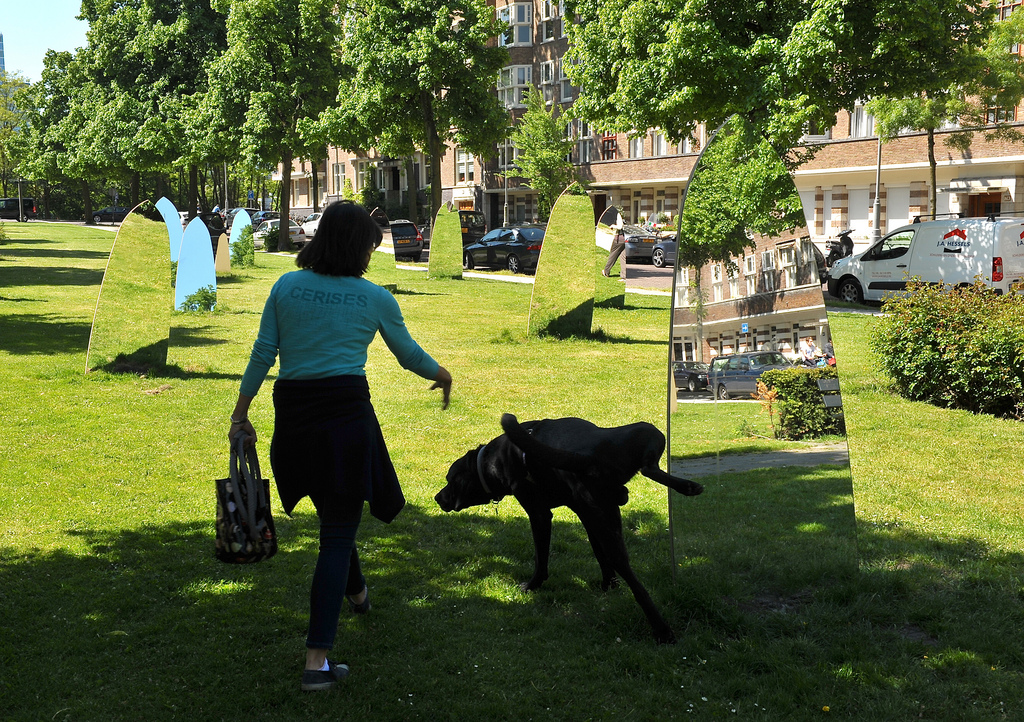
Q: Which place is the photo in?
A: It is at the park.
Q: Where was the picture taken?
A: It was taken at the park.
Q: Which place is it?
A: It is a park.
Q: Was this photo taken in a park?
A: Yes, it was taken in a park.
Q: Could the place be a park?
A: Yes, it is a park.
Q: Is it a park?
A: Yes, it is a park.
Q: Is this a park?
A: Yes, it is a park.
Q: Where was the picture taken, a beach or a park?
A: It was taken at a park.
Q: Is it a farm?
A: No, it is a park.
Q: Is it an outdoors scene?
A: Yes, it is outdoors.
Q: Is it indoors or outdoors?
A: It is outdoors.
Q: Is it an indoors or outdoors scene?
A: It is outdoors.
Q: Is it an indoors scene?
A: No, it is outdoors.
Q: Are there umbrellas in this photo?
A: No, there are no umbrellas.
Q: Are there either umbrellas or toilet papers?
A: No, there are no umbrellas or toilet papers.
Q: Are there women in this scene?
A: Yes, there is a woman.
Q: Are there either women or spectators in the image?
A: Yes, there is a woman.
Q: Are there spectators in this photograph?
A: No, there are no spectators.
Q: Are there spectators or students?
A: No, there are no spectators or students.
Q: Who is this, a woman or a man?
A: This is a woman.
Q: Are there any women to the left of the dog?
A: Yes, there is a woman to the left of the dog.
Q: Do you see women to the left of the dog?
A: Yes, there is a woman to the left of the dog.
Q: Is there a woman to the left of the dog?
A: Yes, there is a woman to the left of the dog.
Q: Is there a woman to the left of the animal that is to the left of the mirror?
A: Yes, there is a woman to the left of the dog.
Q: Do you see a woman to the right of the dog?
A: No, the woman is to the left of the dog.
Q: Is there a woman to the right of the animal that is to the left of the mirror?
A: No, the woman is to the left of the dog.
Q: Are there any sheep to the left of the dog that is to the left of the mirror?
A: No, there is a woman to the left of the dog.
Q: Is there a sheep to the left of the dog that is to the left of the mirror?
A: No, there is a woman to the left of the dog.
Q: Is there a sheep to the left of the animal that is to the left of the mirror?
A: No, there is a woman to the left of the dog.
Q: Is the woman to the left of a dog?
A: Yes, the woman is to the left of a dog.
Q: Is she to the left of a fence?
A: No, the woman is to the left of a dog.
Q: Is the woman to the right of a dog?
A: No, the woman is to the left of a dog.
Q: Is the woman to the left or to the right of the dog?
A: The woman is to the left of the dog.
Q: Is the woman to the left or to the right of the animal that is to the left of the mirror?
A: The woman is to the left of the dog.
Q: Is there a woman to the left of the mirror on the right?
A: Yes, there is a woman to the left of the mirror.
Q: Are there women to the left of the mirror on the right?
A: Yes, there is a woman to the left of the mirror.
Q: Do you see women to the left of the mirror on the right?
A: Yes, there is a woman to the left of the mirror.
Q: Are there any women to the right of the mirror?
A: No, the woman is to the left of the mirror.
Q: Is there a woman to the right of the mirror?
A: No, the woman is to the left of the mirror.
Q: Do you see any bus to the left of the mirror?
A: No, there is a woman to the left of the mirror.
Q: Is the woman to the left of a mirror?
A: Yes, the woman is to the left of a mirror.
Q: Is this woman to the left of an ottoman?
A: No, the woman is to the left of a mirror.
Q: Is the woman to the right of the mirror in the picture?
A: No, the woman is to the left of the mirror.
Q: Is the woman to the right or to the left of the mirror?
A: The woman is to the left of the mirror.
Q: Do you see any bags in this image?
A: Yes, there is a bag.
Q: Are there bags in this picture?
A: Yes, there is a bag.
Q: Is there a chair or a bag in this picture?
A: Yes, there is a bag.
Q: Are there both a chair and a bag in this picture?
A: No, there is a bag but no chairs.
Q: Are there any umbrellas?
A: No, there are no umbrellas.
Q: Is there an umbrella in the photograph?
A: No, there are no umbrellas.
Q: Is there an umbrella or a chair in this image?
A: No, there are no umbrellas or chairs.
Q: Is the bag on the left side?
A: Yes, the bag is on the left of the image.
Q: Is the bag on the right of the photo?
A: No, the bag is on the left of the image.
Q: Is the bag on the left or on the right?
A: The bag is on the left of the image.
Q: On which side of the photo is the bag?
A: The bag is on the left of the image.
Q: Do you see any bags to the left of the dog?
A: Yes, there is a bag to the left of the dog.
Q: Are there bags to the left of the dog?
A: Yes, there is a bag to the left of the dog.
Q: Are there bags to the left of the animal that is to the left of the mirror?
A: Yes, there is a bag to the left of the dog.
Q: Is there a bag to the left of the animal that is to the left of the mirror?
A: Yes, there is a bag to the left of the dog.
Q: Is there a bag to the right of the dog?
A: No, the bag is to the left of the dog.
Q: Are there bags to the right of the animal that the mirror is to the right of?
A: No, the bag is to the left of the dog.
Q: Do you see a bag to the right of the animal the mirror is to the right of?
A: No, the bag is to the left of the dog.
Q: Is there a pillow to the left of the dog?
A: No, there is a bag to the left of the dog.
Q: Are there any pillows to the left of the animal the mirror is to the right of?
A: No, there is a bag to the left of the dog.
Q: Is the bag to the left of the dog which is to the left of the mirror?
A: Yes, the bag is to the left of the dog.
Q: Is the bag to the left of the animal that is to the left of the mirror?
A: Yes, the bag is to the left of the dog.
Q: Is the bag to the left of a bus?
A: No, the bag is to the left of the dog.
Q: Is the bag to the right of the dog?
A: No, the bag is to the left of the dog.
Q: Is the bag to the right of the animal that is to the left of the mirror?
A: No, the bag is to the left of the dog.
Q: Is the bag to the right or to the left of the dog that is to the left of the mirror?
A: The bag is to the left of the dog.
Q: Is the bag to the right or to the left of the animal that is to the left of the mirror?
A: The bag is to the left of the dog.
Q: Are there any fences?
A: No, there are no fences.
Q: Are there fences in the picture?
A: No, there are no fences.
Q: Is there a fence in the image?
A: No, there are no fences.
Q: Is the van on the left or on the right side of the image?
A: The van is on the right of the image.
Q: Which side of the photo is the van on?
A: The van is on the right of the image.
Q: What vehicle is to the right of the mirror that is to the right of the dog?
A: The vehicle is a van.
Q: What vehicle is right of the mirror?
A: The vehicle is a van.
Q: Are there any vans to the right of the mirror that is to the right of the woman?
A: Yes, there is a van to the right of the mirror.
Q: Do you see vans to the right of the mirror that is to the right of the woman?
A: Yes, there is a van to the right of the mirror.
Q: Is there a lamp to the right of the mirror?
A: No, there is a van to the right of the mirror.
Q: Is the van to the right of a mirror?
A: Yes, the van is to the right of a mirror.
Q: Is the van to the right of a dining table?
A: No, the van is to the right of a mirror.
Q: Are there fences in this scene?
A: No, there are no fences.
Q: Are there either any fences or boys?
A: No, there are no fences or boys.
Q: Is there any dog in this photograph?
A: Yes, there is a dog.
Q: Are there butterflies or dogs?
A: Yes, there is a dog.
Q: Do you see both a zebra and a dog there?
A: No, there is a dog but no zebras.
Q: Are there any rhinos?
A: No, there are no rhinos.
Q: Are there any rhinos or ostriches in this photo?
A: No, there are no rhinos or ostriches.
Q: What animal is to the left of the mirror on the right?
A: The animal is a dog.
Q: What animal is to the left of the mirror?
A: The animal is a dog.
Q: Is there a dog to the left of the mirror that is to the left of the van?
A: Yes, there is a dog to the left of the mirror.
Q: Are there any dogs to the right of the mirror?
A: No, the dog is to the left of the mirror.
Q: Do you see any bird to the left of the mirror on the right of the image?
A: No, there is a dog to the left of the mirror.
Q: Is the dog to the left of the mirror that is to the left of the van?
A: Yes, the dog is to the left of the mirror.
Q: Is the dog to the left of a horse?
A: No, the dog is to the left of the mirror.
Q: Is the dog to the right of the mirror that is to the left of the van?
A: No, the dog is to the left of the mirror.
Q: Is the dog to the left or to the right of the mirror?
A: The dog is to the left of the mirror.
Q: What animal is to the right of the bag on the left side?
A: The animal is a dog.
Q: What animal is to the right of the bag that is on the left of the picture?
A: The animal is a dog.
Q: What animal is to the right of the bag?
A: The animal is a dog.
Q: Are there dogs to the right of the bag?
A: Yes, there is a dog to the right of the bag.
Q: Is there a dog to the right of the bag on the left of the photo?
A: Yes, there is a dog to the right of the bag.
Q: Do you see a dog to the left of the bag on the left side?
A: No, the dog is to the right of the bag.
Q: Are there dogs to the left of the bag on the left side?
A: No, the dog is to the right of the bag.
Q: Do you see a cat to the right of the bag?
A: No, there is a dog to the right of the bag.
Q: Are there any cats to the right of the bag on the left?
A: No, there is a dog to the right of the bag.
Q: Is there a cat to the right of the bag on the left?
A: No, there is a dog to the right of the bag.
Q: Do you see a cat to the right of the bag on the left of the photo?
A: No, there is a dog to the right of the bag.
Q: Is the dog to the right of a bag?
A: Yes, the dog is to the right of a bag.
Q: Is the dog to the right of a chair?
A: No, the dog is to the right of a bag.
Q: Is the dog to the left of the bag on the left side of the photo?
A: No, the dog is to the right of the bag.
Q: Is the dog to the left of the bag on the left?
A: No, the dog is to the right of the bag.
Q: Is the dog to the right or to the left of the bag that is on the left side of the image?
A: The dog is to the right of the bag.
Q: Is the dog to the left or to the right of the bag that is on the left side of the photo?
A: The dog is to the right of the bag.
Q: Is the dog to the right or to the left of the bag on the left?
A: The dog is to the right of the bag.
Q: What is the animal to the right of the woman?
A: The animal is a dog.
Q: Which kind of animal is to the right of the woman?
A: The animal is a dog.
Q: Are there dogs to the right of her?
A: Yes, there is a dog to the right of the woman.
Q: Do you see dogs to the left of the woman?
A: No, the dog is to the right of the woman.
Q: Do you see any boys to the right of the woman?
A: No, there is a dog to the right of the woman.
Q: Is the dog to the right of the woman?
A: Yes, the dog is to the right of the woman.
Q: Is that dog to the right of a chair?
A: No, the dog is to the right of the woman.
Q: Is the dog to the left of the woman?
A: No, the dog is to the right of the woman.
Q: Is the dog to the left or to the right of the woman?
A: The dog is to the right of the woman.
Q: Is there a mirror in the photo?
A: Yes, there is a mirror.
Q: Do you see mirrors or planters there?
A: Yes, there is a mirror.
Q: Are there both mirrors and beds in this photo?
A: No, there is a mirror but no beds.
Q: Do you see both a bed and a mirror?
A: No, there is a mirror but no beds.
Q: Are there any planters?
A: No, there are no planters.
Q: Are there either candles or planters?
A: No, there are no planters or candles.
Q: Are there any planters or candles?
A: No, there are no planters or candles.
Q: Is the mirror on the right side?
A: Yes, the mirror is on the right of the image.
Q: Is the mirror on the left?
A: No, the mirror is on the right of the image.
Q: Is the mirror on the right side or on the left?
A: The mirror is on the right of the image.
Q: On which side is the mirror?
A: The mirror is on the right of the image.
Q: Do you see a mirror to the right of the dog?
A: Yes, there is a mirror to the right of the dog.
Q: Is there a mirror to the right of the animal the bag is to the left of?
A: Yes, there is a mirror to the right of the dog.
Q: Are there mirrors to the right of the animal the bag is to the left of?
A: Yes, there is a mirror to the right of the dog.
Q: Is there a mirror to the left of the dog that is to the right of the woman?
A: No, the mirror is to the right of the dog.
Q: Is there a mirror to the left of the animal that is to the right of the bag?
A: No, the mirror is to the right of the dog.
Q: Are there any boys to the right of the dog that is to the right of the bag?
A: No, there is a mirror to the right of the dog.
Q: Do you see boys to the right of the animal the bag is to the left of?
A: No, there is a mirror to the right of the dog.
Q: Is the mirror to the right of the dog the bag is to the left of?
A: Yes, the mirror is to the right of the dog.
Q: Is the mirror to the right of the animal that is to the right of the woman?
A: Yes, the mirror is to the right of the dog.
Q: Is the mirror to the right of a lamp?
A: No, the mirror is to the right of the dog.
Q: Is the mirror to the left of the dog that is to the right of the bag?
A: No, the mirror is to the right of the dog.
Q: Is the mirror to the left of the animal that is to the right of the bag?
A: No, the mirror is to the right of the dog.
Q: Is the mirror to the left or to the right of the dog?
A: The mirror is to the right of the dog.